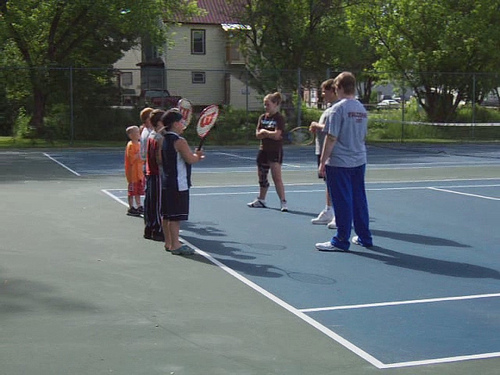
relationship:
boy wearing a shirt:
[125, 126, 147, 218] [123, 142, 147, 186]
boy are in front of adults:
[158, 108, 205, 254] [244, 68, 373, 253]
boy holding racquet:
[158, 104, 205, 254] [195, 103, 220, 155]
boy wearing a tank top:
[158, 104, 205, 254] [161, 132, 193, 192]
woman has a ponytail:
[248, 90, 288, 214] [272, 91, 283, 102]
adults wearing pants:
[313, 70, 377, 251] [322, 161, 375, 249]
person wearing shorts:
[310, 79, 339, 234] [316, 153, 329, 183]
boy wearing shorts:
[158, 104, 205, 254] [157, 175, 191, 223]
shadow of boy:
[180, 218, 286, 281] [158, 108, 205, 254]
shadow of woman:
[269, 204, 319, 221] [248, 90, 288, 214]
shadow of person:
[371, 227, 473, 250] [310, 79, 339, 234]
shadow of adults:
[348, 244, 499, 285] [313, 70, 377, 251]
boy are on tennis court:
[158, 108, 205, 254] [0, 147, 498, 373]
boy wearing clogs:
[158, 104, 205, 254] [168, 243, 200, 257]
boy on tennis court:
[158, 104, 205, 254] [0, 147, 498, 373]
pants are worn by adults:
[322, 161, 375, 249] [313, 70, 377, 251]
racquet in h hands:
[195, 103, 220, 155] [196, 148, 207, 162]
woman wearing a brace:
[248, 90, 288, 214] [256, 165, 272, 190]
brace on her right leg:
[256, 165, 272, 190] [255, 150, 270, 204]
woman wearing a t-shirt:
[248, 90, 288, 214] [259, 112, 288, 148]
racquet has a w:
[195, 103, 220, 155] [198, 110, 217, 128]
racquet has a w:
[176, 97, 196, 134] [177, 105, 190, 123]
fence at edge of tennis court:
[1, 66, 498, 149] [0, 147, 498, 373]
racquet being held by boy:
[195, 103, 220, 155] [158, 104, 205, 254]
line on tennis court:
[43, 153, 82, 179] [0, 147, 498, 373]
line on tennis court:
[100, 189, 129, 206] [0, 147, 498, 373]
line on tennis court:
[180, 238, 386, 370] [0, 147, 498, 373]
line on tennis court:
[305, 284, 499, 316] [0, 147, 498, 373]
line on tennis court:
[382, 343, 500, 371] [0, 147, 498, 373]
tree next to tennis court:
[1, 0, 206, 140] [0, 147, 498, 373]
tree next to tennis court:
[220, 0, 375, 135] [0, 147, 498, 373]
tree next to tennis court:
[369, 1, 500, 127] [0, 147, 498, 373]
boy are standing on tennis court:
[158, 108, 205, 254] [0, 147, 498, 373]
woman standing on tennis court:
[248, 90, 288, 214] [0, 147, 498, 373]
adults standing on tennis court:
[313, 70, 377, 251] [0, 147, 498, 373]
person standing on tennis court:
[310, 79, 339, 234] [0, 147, 498, 373]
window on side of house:
[190, 29, 207, 56] [96, 2, 292, 113]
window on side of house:
[189, 69, 206, 86] [96, 2, 292, 113]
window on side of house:
[119, 70, 135, 86] [96, 2, 292, 113]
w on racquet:
[198, 110, 217, 128] [195, 103, 220, 155]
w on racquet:
[177, 105, 190, 123] [176, 97, 196, 134]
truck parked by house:
[131, 86, 183, 112] [96, 2, 292, 113]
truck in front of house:
[131, 86, 183, 112] [96, 2, 292, 113]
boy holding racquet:
[138, 108, 152, 215] [176, 97, 196, 134]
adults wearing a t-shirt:
[313, 70, 377, 251] [323, 99, 370, 168]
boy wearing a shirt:
[145, 109, 168, 241] [145, 130, 166, 181]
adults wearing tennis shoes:
[313, 70, 377, 251] [315, 234, 370, 253]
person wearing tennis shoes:
[310, 79, 339, 234] [310, 210, 337, 229]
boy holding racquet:
[138, 108, 152, 215] [195, 103, 220, 155]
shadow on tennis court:
[180, 218, 286, 281] [0, 147, 498, 373]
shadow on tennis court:
[269, 204, 319, 221] [0, 147, 498, 373]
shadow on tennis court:
[371, 227, 473, 250] [0, 147, 498, 373]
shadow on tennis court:
[348, 244, 499, 285] [0, 147, 498, 373]